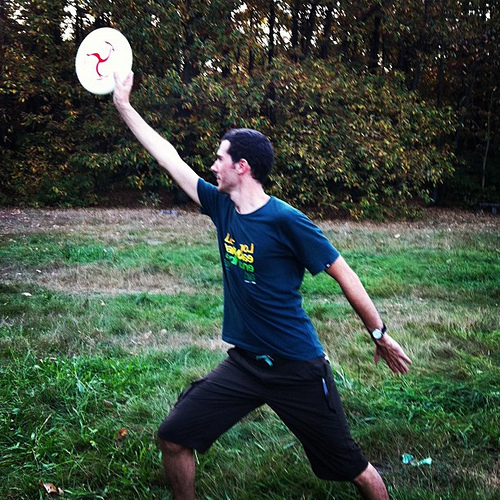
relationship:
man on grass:
[112, 68, 412, 500] [99, 347, 428, 488]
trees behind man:
[2, 3, 494, 206] [112, 68, 412, 500]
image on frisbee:
[85, 39, 114, 81] [69, 25, 134, 102]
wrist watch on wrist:
[371, 322, 388, 341] [369, 325, 406, 346]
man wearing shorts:
[112, 68, 412, 500] [161, 369, 356, 451]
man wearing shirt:
[112, 68, 412, 500] [200, 175, 345, 369]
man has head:
[112, 68, 412, 500] [208, 130, 278, 209]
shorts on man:
[155, 344, 370, 484] [148, 121, 376, 491]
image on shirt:
[218, 227, 260, 288] [190, 177, 340, 362]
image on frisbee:
[77, 37, 119, 81] [72, 23, 134, 96]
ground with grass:
[0, 187, 499, 498] [4, 208, 214, 237]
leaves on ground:
[38, 426, 127, 493] [0, 187, 499, 498]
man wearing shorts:
[161, 114, 469, 459] [155, 344, 370, 484]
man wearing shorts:
[112, 68, 412, 500] [155, 344, 370, 484]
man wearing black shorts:
[112, 68, 412, 500] [142, 341, 451, 461]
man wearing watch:
[112, 68, 412, 500] [366, 320, 391, 347]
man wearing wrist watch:
[112, 68, 412, 500] [362, 322, 394, 346]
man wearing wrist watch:
[112, 68, 412, 500] [366, 317, 386, 338]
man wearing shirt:
[112, 68, 412, 500] [191, 162, 338, 354]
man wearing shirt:
[112, 68, 412, 500] [190, 177, 340, 362]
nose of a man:
[206, 167, 219, 181] [194, 118, 328, 478]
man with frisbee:
[112, 68, 412, 500] [71, 19, 131, 100]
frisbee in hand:
[71, 19, 131, 100] [107, 69, 137, 112]